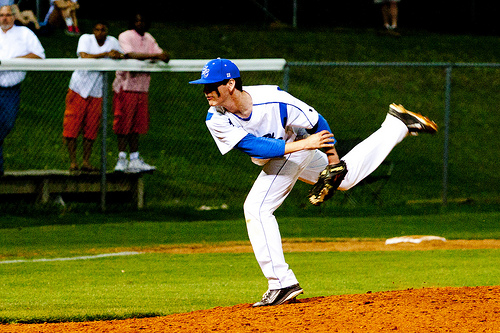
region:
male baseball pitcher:
[184, 40, 442, 309]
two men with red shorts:
[55, 10, 166, 178]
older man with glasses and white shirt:
[2, 0, 45, 161]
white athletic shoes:
[108, 140, 158, 180]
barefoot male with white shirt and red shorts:
[60, 15, 115, 180]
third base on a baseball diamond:
[371, 213, 462, 269]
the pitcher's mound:
[153, 272, 348, 329]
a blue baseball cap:
[176, 47, 252, 92]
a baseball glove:
[305, 155, 351, 215]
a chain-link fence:
[322, 50, 499, 102]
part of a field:
[128, 209, 151, 294]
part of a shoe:
[270, 287, 282, 303]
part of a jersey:
[273, 97, 290, 107]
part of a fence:
[448, 163, 456, 193]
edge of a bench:
[57, 168, 63, 178]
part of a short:
[118, 110, 124, 132]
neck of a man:
[236, 85, 243, 99]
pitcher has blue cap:
[188, 48, 237, 115]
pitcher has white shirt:
[205, 88, 290, 149]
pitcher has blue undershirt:
[242, 129, 294, 166]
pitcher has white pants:
[223, 141, 368, 215]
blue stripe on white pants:
[250, 155, 281, 263]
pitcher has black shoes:
[250, 263, 287, 308]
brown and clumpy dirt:
[297, 283, 488, 327]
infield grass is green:
[13, 259, 176, 310]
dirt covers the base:
[380, 223, 461, 265]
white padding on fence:
[75, 41, 254, 93]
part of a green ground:
[313, 225, 364, 291]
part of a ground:
[341, 292, 372, 312]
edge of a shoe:
[256, 289, 302, 325]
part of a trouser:
[256, 210, 289, 252]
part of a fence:
[158, 156, 209, 213]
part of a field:
[156, 236, 205, 285]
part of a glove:
[295, 155, 324, 222]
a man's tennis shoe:
[385, 101, 437, 137]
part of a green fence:
[285, 55, 495, 210]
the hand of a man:
[302, 130, 334, 146]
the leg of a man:
[308, 115, 404, 190]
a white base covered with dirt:
[380, 225, 445, 242]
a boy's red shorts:
[110, 90, 151, 135]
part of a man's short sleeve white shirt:
[0, 22, 41, 82]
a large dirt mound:
[0, 282, 497, 328]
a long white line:
[4, 247, 146, 262]